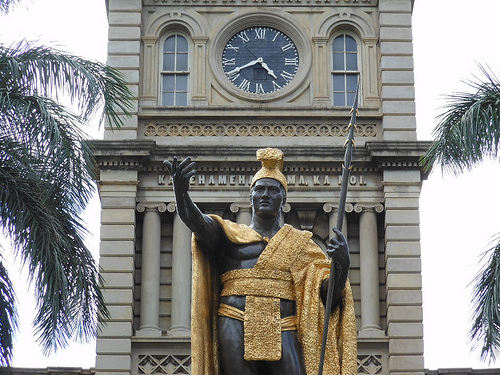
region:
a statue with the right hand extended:
[153, 143, 361, 373]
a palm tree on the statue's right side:
[0, 42, 134, 373]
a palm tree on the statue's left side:
[423, 69, 498, 367]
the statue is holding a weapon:
[300, 82, 363, 373]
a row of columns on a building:
[139, 200, 389, 327]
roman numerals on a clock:
[203, 8, 306, 101]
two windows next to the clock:
[148, 8, 368, 108]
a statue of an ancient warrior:
[161, 148, 365, 373]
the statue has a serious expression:
[249, 173, 287, 227]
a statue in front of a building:
[159, 134, 388, 374]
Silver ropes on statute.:
[218, 249, 312, 371]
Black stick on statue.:
[322, 59, 357, 354]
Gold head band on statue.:
[240, 142, 287, 189]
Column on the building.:
[135, 191, 165, 366]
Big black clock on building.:
[208, 5, 329, 116]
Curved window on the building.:
[141, 8, 201, 108]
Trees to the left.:
[4, 31, 102, 348]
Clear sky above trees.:
[440, 18, 482, 55]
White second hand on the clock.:
[247, 49, 275, 79]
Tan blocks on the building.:
[84, 321, 131, 369]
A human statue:
[160, 74, 372, 374]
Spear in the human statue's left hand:
[316, 74, 365, 371]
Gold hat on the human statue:
[250, 145, 287, 189]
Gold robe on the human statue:
[190, 211, 357, 372]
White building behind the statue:
[77, 2, 438, 371]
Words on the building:
[156, 171, 366, 188]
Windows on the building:
[140, 8, 375, 108]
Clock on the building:
[217, 23, 299, 95]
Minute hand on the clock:
[226, 56, 262, 76]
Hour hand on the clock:
[257, 56, 277, 77]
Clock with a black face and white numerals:
[202, 7, 316, 104]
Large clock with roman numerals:
[205, 8, 308, 104]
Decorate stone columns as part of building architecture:
[130, 199, 167, 346]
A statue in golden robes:
[150, 71, 375, 373]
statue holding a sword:
[161, 86, 365, 373]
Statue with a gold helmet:
[237, 132, 296, 221]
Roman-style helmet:
[244, 146, 293, 215]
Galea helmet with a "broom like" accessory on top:
[243, 140, 296, 214]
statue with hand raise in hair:
[169, 80, 382, 374]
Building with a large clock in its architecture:
[70, 0, 452, 374]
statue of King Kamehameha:
[171, 76, 358, 373]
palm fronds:
[433, 61, 497, 358]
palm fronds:
[0, 41, 130, 373]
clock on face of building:
[211, 6, 311, 103]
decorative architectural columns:
[136, 193, 384, 340]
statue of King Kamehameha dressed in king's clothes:
[171, 93, 363, 373]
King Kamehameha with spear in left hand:
[170, 99, 362, 373]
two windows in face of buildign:
[142, 10, 380, 105]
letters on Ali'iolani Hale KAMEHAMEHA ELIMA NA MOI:
[155, 172, 365, 182]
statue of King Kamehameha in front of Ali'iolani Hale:
[0, 0, 498, 372]